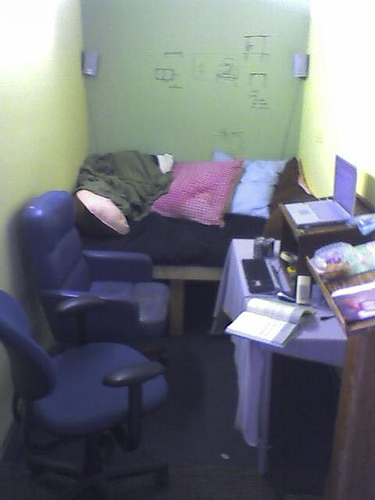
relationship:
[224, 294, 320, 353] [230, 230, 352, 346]
book on desk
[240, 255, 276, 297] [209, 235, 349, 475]
keyboard on table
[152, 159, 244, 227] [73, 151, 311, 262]
pillow on bed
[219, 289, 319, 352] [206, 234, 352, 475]
book on table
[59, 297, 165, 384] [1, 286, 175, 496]
armrests on chair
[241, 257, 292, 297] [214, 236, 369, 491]
keyboard on table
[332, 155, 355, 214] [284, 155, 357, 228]
screen of laptop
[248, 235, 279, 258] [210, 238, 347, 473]
cans on desk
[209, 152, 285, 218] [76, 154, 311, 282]
blue pillow on bed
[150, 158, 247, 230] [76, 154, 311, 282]
pillow on bed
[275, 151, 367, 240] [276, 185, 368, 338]
laptop on desk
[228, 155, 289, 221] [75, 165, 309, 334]
blue pillow on bed